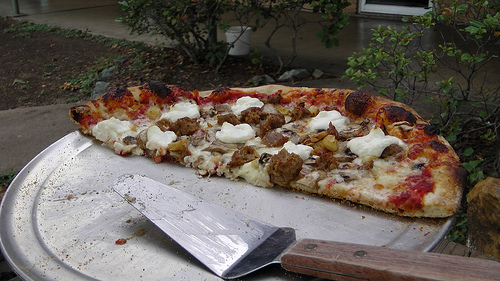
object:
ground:
[450, 105, 482, 128]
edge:
[345, 88, 418, 126]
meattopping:
[264, 127, 293, 146]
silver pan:
[0, 132, 455, 279]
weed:
[25, 17, 132, 103]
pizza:
[75, 50, 464, 218]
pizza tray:
[13, 121, 451, 268]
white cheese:
[149, 105, 399, 165]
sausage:
[260, 135, 318, 194]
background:
[327, 32, 471, 107]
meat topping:
[215, 113, 240, 125]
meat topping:
[379, 143, 404, 158]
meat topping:
[171, 115, 199, 135]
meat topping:
[259, 113, 285, 130]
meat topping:
[266, 148, 303, 187]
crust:
[67, 71, 470, 221]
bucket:
[220, 26, 255, 54]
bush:
[126, 6, 346, 67]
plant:
[357, 1, 498, 240]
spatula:
[108, 170, 497, 278]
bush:
[345, 4, 497, 244]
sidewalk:
[4, 102, 74, 184]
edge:
[26, 18, 161, 52]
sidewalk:
[22, 5, 495, 115]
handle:
[285, 236, 499, 279]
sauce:
[391, 167, 435, 210]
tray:
[1, 128, 453, 279]